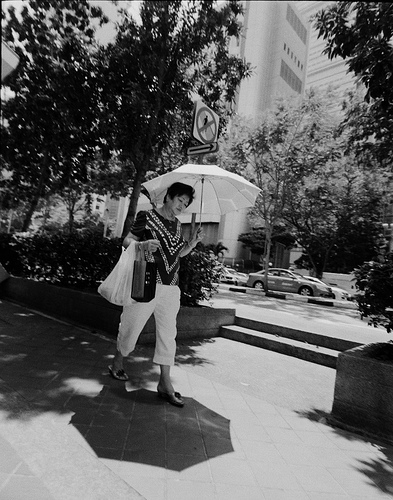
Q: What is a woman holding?
A: An umbrella.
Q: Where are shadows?
A: On the ground.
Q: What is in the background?
A: A building.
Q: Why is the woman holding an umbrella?
A: Sun protection.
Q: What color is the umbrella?
A: White.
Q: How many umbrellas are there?
A: One.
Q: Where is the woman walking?
A: Sidewalk.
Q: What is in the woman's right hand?
A: Bags.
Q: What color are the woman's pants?
A: White.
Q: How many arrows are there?
A: One.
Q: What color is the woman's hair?
A: Black.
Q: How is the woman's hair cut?
A: Short.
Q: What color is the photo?
A: Black and white.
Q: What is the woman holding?
A: Umbrella.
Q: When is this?
A: During the day time.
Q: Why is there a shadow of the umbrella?
A: Sunny.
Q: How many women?
A: One.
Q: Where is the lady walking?
A: On the sidewalk.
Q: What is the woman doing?
A: Walking.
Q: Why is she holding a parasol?
A: To block the sun.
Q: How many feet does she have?
A: Two.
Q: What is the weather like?
A: Sunny.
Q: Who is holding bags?
A: The lady.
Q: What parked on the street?
A: Cars.